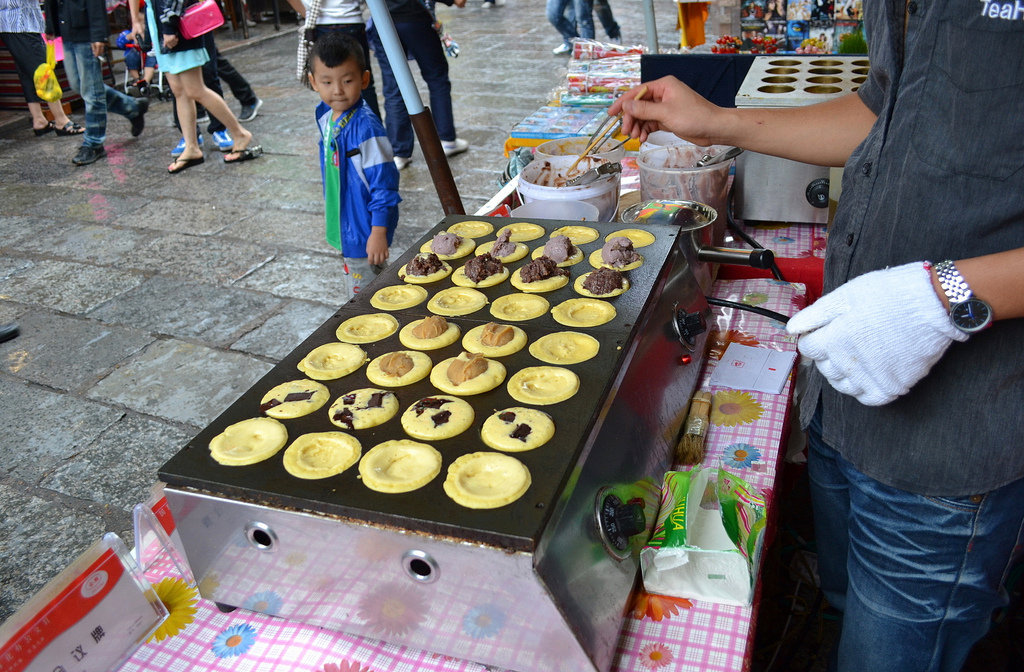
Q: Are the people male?
A: No, they are both male and female.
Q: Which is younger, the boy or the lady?
A: The boy is younger than the lady.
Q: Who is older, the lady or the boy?
A: The lady is older than the boy.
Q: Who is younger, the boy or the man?
A: The boy is younger than the man.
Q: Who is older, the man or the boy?
A: The man is older than the boy.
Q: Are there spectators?
A: No, there are no spectators.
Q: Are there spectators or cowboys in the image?
A: No, there are no spectators or cowboys.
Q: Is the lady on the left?
A: Yes, the lady is on the left of the image.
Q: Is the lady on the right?
A: No, the lady is on the left of the image.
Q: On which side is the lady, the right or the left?
A: The lady is on the left of the image.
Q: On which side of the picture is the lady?
A: The lady is on the left of the image.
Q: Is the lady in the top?
A: Yes, the lady is in the top of the image.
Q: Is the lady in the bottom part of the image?
A: No, the lady is in the top of the image.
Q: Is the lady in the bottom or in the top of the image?
A: The lady is in the top of the image.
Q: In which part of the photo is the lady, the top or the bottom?
A: The lady is in the top of the image.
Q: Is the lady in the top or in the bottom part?
A: The lady is in the top of the image.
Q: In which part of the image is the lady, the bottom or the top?
A: The lady is in the top of the image.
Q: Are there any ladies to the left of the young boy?
A: Yes, there is a lady to the left of the boy.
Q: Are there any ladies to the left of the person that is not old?
A: Yes, there is a lady to the left of the boy.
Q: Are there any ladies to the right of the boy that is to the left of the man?
A: No, the lady is to the left of the boy.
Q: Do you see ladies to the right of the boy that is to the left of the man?
A: No, the lady is to the left of the boy.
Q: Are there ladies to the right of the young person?
A: No, the lady is to the left of the boy.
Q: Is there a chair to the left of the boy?
A: No, there is a lady to the left of the boy.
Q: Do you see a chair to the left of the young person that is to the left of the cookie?
A: No, there is a lady to the left of the boy.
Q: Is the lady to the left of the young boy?
A: Yes, the lady is to the left of the boy.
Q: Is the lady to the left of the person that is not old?
A: Yes, the lady is to the left of the boy.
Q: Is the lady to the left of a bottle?
A: No, the lady is to the left of the boy.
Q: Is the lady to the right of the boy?
A: No, the lady is to the left of the boy.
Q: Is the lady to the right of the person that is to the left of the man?
A: No, the lady is to the left of the boy.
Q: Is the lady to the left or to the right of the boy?
A: The lady is to the left of the boy.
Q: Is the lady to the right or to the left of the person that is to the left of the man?
A: The lady is to the left of the boy.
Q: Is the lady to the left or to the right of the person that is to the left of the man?
A: The lady is to the left of the boy.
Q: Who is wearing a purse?
A: The lady is wearing a purse.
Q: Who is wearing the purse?
A: The lady is wearing a purse.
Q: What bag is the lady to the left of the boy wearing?
A: The lady is wearing a purse.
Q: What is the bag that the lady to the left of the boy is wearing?
A: The bag is a purse.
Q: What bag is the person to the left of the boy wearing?
A: The lady is wearing a purse.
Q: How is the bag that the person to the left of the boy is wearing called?
A: The bag is a purse.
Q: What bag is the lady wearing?
A: The lady is wearing a purse.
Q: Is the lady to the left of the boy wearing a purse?
A: Yes, the lady is wearing a purse.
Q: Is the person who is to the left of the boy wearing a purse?
A: Yes, the lady is wearing a purse.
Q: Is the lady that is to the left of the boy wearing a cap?
A: No, the lady is wearing a purse.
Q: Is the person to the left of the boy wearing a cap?
A: No, the lady is wearing a purse.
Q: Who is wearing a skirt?
A: The lady is wearing a skirt.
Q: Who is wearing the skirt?
A: The lady is wearing a skirt.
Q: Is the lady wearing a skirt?
A: Yes, the lady is wearing a skirt.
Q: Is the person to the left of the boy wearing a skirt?
A: Yes, the lady is wearing a skirt.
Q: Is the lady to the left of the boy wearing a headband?
A: No, the lady is wearing a skirt.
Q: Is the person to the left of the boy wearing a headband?
A: No, the lady is wearing a skirt.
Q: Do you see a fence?
A: No, there are no fences.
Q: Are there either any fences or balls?
A: No, there are no fences or balls.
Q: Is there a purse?
A: Yes, there is a purse.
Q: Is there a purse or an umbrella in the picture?
A: Yes, there is a purse.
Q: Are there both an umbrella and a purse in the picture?
A: No, there is a purse but no umbrellas.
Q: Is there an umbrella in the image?
A: No, there are no umbrellas.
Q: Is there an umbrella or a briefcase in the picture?
A: No, there are no umbrellas or briefcases.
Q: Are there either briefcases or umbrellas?
A: No, there are no umbrellas or briefcases.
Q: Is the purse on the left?
A: Yes, the purse is on the left of the image.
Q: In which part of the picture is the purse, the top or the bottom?
A: The purse is in the top of the image.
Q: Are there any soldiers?
A: No, there are no soldiers.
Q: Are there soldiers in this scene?
A: No, there are no soldiers.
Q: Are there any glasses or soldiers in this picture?
A: No, there are no soldiers or glasses.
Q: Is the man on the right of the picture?
A: Yes, the man is on the right of the image.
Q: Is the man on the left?
A: No, the man is on the right of the image.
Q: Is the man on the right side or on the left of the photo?
A: The man is on the right of the image.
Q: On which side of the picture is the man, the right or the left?
A: The man is on the right of the image.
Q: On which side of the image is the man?
A: The man is on the right of the image.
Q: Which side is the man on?
A: The man is on the right of the image.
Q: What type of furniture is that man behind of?
A: The man is behind the table.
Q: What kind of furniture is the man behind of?
A: The man is behind the table.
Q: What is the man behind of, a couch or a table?
A: The man is behind a table.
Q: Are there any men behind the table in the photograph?
A: Yes, there is a man behind the table.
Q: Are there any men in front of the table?
A: No, the man is behind the table.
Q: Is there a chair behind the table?
A: No, there is a man behind the table.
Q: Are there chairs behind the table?
A: No, there is a man behind the table.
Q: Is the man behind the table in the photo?
A: Yes, the man is behind the table.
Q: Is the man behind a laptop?
A: No, the man is behind the table.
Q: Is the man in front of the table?
A: No, the man is behind the table.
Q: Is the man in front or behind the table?
A: The man is behind the table.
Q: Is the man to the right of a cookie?
A: Yes, the man is to the right of a cookie.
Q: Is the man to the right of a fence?
A: No, the man is to the right of a cookie.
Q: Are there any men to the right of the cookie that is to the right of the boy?
A: Yes, there is a man to the right of the cookie.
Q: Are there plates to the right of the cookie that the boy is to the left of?
A: No, there is a man to the right of the cookie.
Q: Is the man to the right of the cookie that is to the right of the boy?
A: Yes, the man is to the right of the cookie.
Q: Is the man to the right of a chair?
A: No, the man is to the right of the cookie.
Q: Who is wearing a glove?
A: The man is wearing a glove.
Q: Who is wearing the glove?
A: The man is wearing a glove.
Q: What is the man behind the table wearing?
A: The man is wearing a glove.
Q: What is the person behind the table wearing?
A: The man is wearing a glove.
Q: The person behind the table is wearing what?
A: The man is wearing a glove.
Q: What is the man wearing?
A: The man is wearing a glove.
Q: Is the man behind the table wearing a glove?
A: Yes, the man is wearing a glove.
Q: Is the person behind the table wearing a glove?
A: Yes, the man is wearing a glove.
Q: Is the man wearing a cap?
A: No, the man is wearing a glove.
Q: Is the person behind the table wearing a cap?
A: No, the man is wearing a glove.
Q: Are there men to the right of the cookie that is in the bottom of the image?
A: Yes, there is a man to the right of the cookie.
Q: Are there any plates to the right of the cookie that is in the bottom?
A: No, there is a man to the right of the cookie.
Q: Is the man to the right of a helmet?
A: No, the man is to the right of a cookie.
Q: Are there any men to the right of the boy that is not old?
A: Yes, there is a man to the right of the boy.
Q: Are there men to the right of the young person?
A: Yes, there is a man to the right of the boy.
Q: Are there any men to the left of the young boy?
A: No, the man is to the right of the boy.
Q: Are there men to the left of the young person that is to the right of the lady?
A: No, the man is to the right of the boy.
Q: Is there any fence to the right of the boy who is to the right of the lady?
A: No, there is a man to the right of the boy.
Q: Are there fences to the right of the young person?
A: No, there is a man to the right of the boy.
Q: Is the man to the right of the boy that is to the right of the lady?
A: Yes, the man is to the right of the boy.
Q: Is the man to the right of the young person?
A: Yes, the man is to the right of the boy.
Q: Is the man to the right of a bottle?
A: No, the man is to the right of the boy.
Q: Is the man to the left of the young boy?
A: No, the man is to the right of the boy.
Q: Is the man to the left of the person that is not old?
A: No, the man is to the right of the boy.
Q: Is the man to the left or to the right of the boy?
A: The man is to the right of the boy.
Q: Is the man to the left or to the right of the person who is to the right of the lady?
A: The man is to the right of the boy.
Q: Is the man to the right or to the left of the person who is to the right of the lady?
A: The man is to the right of the boy.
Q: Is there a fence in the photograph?
A: No, there are no fences.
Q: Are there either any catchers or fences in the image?
A: No, there are no fences or catchers.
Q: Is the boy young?
A: Yes, the boy is young.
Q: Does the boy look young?
A: Yes, the boy is young.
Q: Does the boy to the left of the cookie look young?
A: Yes, the boy is young.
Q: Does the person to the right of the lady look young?
A: Yes, the boy is young.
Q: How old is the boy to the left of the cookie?
A: The boy is young.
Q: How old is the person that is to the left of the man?
A: The boy is young.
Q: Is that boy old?
A: No, the boy is young.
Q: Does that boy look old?
A: No, the boy is young.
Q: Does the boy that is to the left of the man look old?
A: No, the boy is young.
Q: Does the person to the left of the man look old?
A: No, the boy is young.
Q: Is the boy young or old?
A: The boy is young.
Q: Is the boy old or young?
A: The boy is young.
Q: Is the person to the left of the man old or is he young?
A: The boy is young.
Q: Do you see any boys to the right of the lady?
A: Yes, there is a boy to the right of the lady.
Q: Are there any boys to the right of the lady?
A: Yes, there is a boy to the right of the lady.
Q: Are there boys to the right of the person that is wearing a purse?
A: Yes, there is a boy to the right of the lady.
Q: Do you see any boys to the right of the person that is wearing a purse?
A: Yes, there is a boy to the right of the lady.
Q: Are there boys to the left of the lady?
A: No, the boy is to the right of the lady.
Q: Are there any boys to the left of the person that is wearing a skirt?
A: No, the boy is to the right of the lady.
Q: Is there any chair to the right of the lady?
A: No, there is a boy to the right of the lady.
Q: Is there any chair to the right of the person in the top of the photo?
A: No, there is a boy to the right of the lady.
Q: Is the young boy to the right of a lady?
A: Yes, the boy is to the right of a lady.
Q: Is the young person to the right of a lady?
A: Yes, the boy is to the right of a lady.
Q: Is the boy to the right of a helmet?
A: No, the boy is to the right of a lady.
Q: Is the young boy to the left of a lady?
A: No, the boy is to the right of a lady.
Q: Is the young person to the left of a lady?
A: No, the boy is to the right of a lady.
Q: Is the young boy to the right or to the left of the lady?
A: The boy is to the right of the lady.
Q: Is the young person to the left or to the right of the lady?
A: The boy is to the right of the lady.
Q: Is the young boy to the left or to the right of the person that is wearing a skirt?
A: The boy is to the right of the lady.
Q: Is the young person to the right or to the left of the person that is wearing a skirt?
A: The boy is to the right of the lady.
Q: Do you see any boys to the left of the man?
A: Yes, there is a boy to the left of the man.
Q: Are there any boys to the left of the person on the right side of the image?
A: Yes, there is a boy to the left of the man.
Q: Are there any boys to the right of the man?
A: No, the boy is to the left of the man.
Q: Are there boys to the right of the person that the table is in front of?
A: No, the boy is to the left of the man.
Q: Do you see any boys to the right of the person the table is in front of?
A: No, the boy is to the left of the man.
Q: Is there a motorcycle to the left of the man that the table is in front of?
A: No, there is a boy to the left of the man.